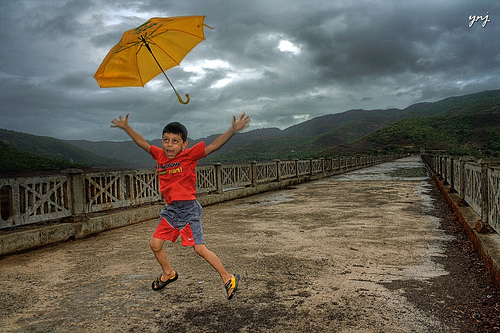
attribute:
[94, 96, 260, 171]
hands — up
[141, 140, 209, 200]
shirt — red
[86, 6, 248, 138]
umbrella — yellow, in air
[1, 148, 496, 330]
road — Rough, Rough well-traveled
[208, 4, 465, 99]
sky — dark, stormy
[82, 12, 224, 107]
umbrella — yellow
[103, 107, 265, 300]
boy — young, with lots of emotions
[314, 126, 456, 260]
path — part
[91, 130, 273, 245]
boy — little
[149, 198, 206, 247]
shorts — grey and red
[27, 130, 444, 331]
bridge — part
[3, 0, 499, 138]
dark clouds — Ominous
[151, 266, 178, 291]
shoes — yellow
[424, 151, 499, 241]
fence — ornate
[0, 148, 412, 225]
fence — ornate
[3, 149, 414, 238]
railing — for Safety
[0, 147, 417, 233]
fence — ornate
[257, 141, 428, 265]
bridge — long, concrete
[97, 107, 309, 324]
boy — jumping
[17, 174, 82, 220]
fence — part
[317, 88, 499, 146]
hill — covered, grass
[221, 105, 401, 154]
hill — covered, grass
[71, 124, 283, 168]
hill — covered, grass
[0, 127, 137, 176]
hill — covered, grass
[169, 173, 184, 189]
shirt — part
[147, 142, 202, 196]
tshirt — red, with front design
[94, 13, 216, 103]
umbrella — bright, yellow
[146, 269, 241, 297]
sandals — Gray and yellow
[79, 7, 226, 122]
umbrella — yellow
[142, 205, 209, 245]
shorts. — grey, red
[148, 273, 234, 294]
sandals — yellow